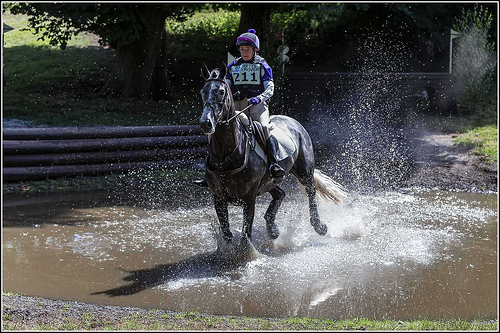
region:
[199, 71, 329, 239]
black and white horse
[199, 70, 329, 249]
horse walking in water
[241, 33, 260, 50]
white and blue helmet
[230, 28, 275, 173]
man riding black horse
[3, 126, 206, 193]
grey wood barrier fence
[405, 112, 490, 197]
brown dirt walking trail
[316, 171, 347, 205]
white tail on horse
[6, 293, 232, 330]
grey stones in grass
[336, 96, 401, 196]
water splashed from horse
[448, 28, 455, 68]
white flag on pole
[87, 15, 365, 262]
a boy riding a horse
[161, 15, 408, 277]
a boy riding a black horse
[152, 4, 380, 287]
a boy riding a running horse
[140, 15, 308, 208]
a boy sitting on a sadle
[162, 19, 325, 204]
a boy wearing a hat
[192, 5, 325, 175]
a boy wearing a number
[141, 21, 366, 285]
a black horse running through water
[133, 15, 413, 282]
a horse wearing a saddle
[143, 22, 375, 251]
a black horse wearing a saddle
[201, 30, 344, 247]
woman riding a horse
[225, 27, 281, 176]
woman in a purple riding outfit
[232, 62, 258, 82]
white contestant number with black lettering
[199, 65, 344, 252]
black horse with a white tail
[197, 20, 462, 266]
horse and rider splashing in the water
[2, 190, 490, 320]
brown murky water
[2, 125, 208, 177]
long wooden fence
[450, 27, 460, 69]
white flag on a pole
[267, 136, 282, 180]
black riding boots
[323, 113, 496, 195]
mud path leading to the water hole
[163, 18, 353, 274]
a player riding a horse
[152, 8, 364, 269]
a number 211 player riding a horse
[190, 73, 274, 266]
a horse with white mark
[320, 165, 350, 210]
a horse tail wagging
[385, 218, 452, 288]
a pond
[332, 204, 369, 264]
a splash of water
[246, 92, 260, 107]
a purple gloves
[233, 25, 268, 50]
a purple bonnet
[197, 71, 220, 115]
a white mark of the horse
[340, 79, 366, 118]
splash of water in the air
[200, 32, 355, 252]
rider on black horse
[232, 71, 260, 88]
number 211 on rider's bib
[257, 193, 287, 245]
leg of horse in water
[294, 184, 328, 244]
leg of horse in water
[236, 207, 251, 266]
leg of horse in water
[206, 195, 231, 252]
leg of horse in water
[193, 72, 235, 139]
head of black horse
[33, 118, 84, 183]
barrier made of wood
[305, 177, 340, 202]
tail of horse waving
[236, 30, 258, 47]
hat on rider's head